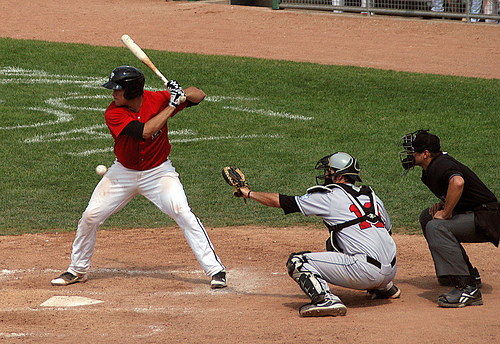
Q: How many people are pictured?
A: 3.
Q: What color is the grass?
A: Green.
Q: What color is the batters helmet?
A: Black.